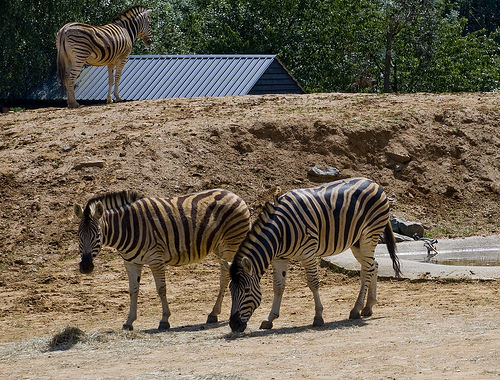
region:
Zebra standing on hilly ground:
[57, 6, 159, 106]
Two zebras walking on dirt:
[73, 177, 402, 331]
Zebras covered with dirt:
[77, 182, 391, 335]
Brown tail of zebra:
[382, 222, 403, 277]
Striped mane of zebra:
[86, 188, 141, 211]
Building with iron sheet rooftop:
[32, 50, 308, 107]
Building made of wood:
[250, 59, 303, 101]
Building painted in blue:
[35, 51, 302, 107]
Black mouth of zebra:
[77, 252, 95, 274]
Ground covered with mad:
[0, 92, 498, 313]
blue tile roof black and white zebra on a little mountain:
[54, 7, 161, 107]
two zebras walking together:
[74, 175, 403, 337]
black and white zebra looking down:
[226, 177, 403, 334]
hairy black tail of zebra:
[383, 222, 401, 281]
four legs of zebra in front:
[259, 238, 385, 331]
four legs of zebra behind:
[115, 259, 238, 331]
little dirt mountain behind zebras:
[0, 86, 494, 318]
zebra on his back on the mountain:
[53, 3, 158, 108]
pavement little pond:
[322, 228, 497, 279]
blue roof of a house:
[25, 50, 308, 106]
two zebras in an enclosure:
[75, 173, 393, 331]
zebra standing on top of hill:
[57, 5, 152, 96]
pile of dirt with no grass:
[0, 95, 496, 228]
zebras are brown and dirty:
[82, 176, 393, 311]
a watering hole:
[317, 205, 497, 283]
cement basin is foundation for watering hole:
[327, 231, 497, 277]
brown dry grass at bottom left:
[1, 316, 194, 368]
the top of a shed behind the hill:
[55, 48, 297, 98]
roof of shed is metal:
[41, 42, 304, 95]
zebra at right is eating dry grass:
[227, 180, 412, 335]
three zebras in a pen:
[1, 0, 467, 360]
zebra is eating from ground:
[213, 160, 411, 348]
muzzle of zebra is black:
[223, 310, 249, 337]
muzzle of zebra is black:
[74, 248, 96, 278]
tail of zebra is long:
[383, 210, 402, 287]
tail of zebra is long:
[46, 26, 73, 92]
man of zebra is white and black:
[82, 178, 140, 215]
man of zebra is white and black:
[228, 193, 282, 263]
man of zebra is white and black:
[111, 4, 148, 26]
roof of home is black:
[125, 43, 312, 111]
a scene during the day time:
[10, 15, 496, 360]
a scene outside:
[3, 1, 473, 377]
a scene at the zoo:
[11, 0, 495, 337]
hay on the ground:
[25, 305, 216, 362]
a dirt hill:
[10, 100, 498, 222]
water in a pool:
[330, 215, 485, 282]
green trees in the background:
[2, 0, 496, 115]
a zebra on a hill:
[40, 0, 155, 112]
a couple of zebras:
[50, 165, 424, 342]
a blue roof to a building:
[52, 31, 313, 141]